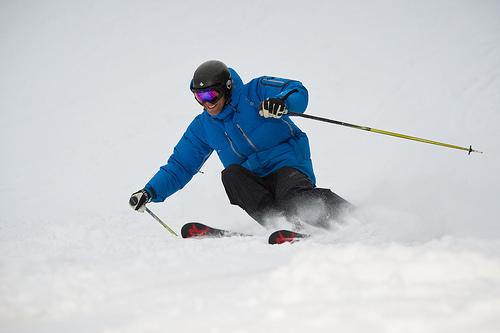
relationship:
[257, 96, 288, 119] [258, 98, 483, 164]
hand holding ski pole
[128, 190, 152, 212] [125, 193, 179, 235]
hand holding ski pole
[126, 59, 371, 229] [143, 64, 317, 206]
man wearing jacket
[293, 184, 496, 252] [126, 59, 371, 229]
snow being kicked up by man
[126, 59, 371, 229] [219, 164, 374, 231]
man wearing pants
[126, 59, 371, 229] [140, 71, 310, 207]
man wearing jacket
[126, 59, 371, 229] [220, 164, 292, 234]
man has leg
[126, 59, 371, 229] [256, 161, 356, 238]
man has leg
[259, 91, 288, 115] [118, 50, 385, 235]
hand of skier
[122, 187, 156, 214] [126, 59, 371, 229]
hand of man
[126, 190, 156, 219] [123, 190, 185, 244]
hand holding ski pole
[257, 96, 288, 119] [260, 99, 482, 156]
hand holding ski pole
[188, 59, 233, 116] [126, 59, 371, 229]
helmet on man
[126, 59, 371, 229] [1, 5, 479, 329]
man in snow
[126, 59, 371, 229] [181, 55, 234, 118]
man wearing helmet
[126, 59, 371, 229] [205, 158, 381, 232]
man wearing pants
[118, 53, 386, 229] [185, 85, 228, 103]
man wearing goggles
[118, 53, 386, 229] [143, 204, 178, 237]
man holding ski pole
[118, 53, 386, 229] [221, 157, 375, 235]
man wearing pants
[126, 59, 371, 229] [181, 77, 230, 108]
man wearing goggles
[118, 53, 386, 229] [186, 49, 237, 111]
man has on a helmet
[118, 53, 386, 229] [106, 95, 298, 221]
man wearing gloves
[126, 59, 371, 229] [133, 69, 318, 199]
man in a jacket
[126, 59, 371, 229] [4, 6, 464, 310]
man coming down slope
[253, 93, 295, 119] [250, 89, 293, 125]
hand in glove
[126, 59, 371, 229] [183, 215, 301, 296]
man with red design on bottom